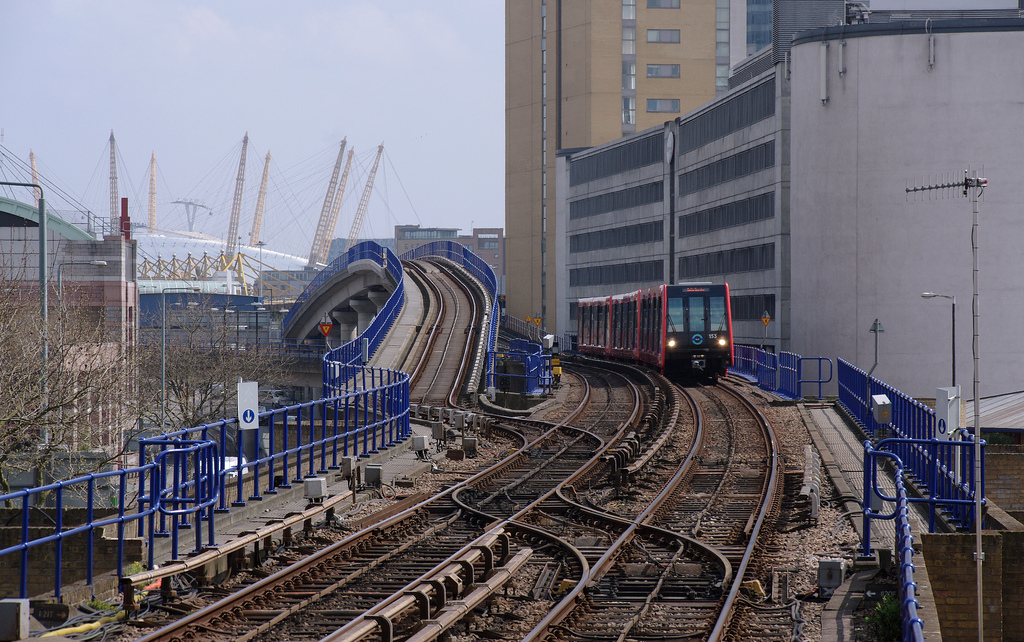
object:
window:
[596, 194, 606, 215]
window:
[647, 64, 681, 78]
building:
[505, 0, 716, 344]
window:
[646, 98, 680, 113]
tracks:
[140, 259, 777, 641]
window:
[734, 246, 750, 273]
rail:
[401, 259, 477, 400]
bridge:
[281, 240, 498, 399]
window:
[710, 297, 728, 331]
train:
[578, 282, 734, 377]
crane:
[318, 146, 355, 264]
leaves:
[0, 234, 304, 508]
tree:
[103, 288, 303, 490]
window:
[679, 242, 775, 278]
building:
[554, 17, 1024, 400]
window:
[640, 260, 655, 282]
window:
[626, 262, 641, 283]